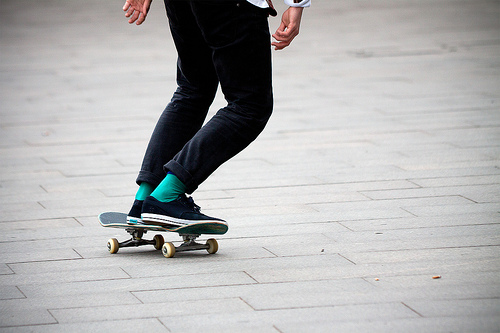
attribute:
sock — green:
[157, 171, 185, 202]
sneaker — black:
[138, 202, 205, 217]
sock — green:
[139, 182, 151, 195]